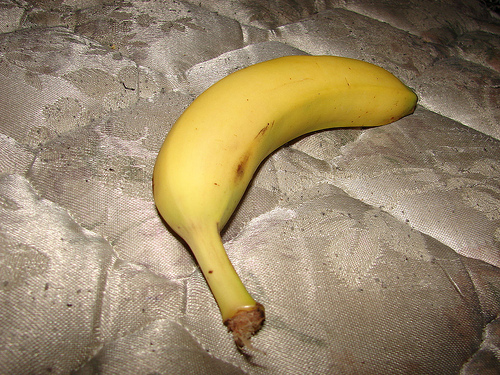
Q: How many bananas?
A: One.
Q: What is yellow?
A: Banana.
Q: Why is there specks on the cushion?
A: It is dirty.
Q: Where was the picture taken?
A: Bedroom.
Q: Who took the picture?
A: Man.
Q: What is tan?
A: Cushion.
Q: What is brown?
A: Banana stem.